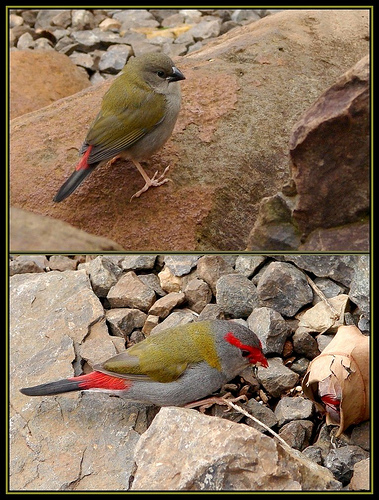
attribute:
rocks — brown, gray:
[256, 259, 312, 311]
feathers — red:
[74, 365, 123, 389]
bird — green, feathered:
[21, 318, 268, 404]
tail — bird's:
[20, 363, 125, 396]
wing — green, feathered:
[82, 86, 168, 167]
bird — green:
[50, 51, 187, 203]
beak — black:
[168, 68, 185, 84]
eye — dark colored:
[238, 350, 251, 357]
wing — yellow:
[100, 320, 221, 382]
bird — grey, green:
[63, 25, 221, 210]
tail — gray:
[18, 371, 128, 396]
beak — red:
[242, 346, 273, 374]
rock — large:
[26, 246, 360, 340]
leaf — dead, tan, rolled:
[301, 324, 374, 430]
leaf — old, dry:
[317, 367, 344, 424]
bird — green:
[51, 52, 178, 208]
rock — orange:
[8, 9, 369, 247]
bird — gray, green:
[57, 49, 208, 210]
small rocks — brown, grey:
[10, 252, 377, 497]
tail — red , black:
[22, 372, 112, 399]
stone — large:
[303, 115, 363, 216]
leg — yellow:
[128, 161, 152, 177]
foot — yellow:
[135, 171, 168, 199]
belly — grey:
[145, 374, 210, 397]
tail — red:
[72, 375, 118, 391]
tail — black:
[22, 362, 90, 410]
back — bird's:
[107, 319, 215, 352]